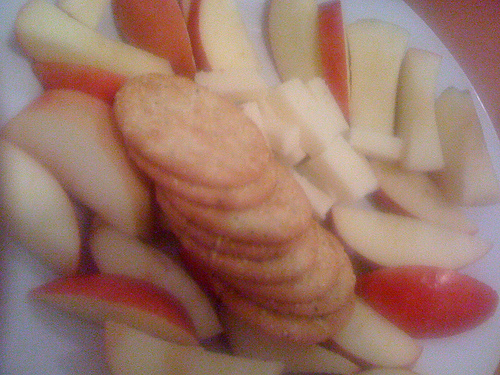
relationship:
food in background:
[0, 0, 498, 374] [33, 16, 443, 358]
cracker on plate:
[107, 70, 313, 186] [5, 4, 482, 363]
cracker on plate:
[227, 223, 359, 316] [5, 4, 482, 363]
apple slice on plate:
[427, 85, 499, 207] [5, 4, 482, 363]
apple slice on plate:
[393, 42, 446, 172] [5, 4, 482, 363]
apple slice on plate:
[344, 15, 411, 136] [5, 4, 482, 363]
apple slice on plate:
[317, 0, 352, 125] [5, 4, 482, 363]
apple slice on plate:
[267, 0, 325, 81] [5, 4, 482, 363]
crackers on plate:
[113, 70, 358, 345] [5, 4, 482, 363]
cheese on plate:
[193, 66, 270, 103] [5, 4, 482, 363]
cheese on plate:
[265, 76, 341, 157] [5, 4, 482, 363]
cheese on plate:
[307, 131, 381, 204] [5, 4, 482, 363]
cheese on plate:
[346, 119, 405, 165] [5, 4, 482, 363]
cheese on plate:
[264, 107, 302, 154] [5, 4, 482, 363]